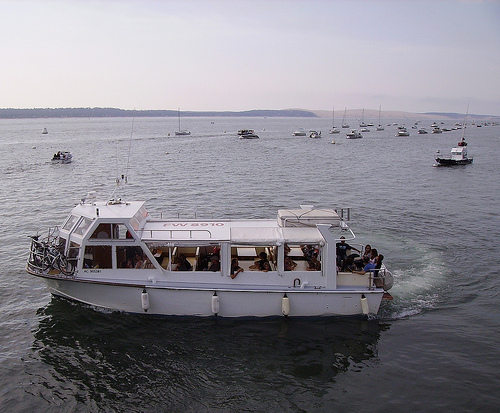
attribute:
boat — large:
[24, 197, 396, 320]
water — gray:
[0, 117, 493, 405]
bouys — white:
[134, 284, 376, 320]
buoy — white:
[278, 295, 290, 316]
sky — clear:
[0, 2, 497, 119]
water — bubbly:
[138, 140, 498, 232]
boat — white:
[24, 170, 399, 318]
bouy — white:
[51, 132, 104, 172]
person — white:
[367, 251, 381, 268]